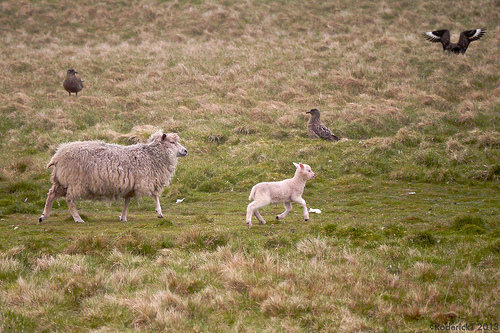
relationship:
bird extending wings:
[421, 16, 489, 58] [421, 23, 486, 41]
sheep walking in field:
[42, 120, 180, 228] [1, 3, 493, 333]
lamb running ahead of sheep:
[239, 152, 316, 224] [42, 120, 180, 228]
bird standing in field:
[303, 102, 342, 148] [1, 3, 493, 333]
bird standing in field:
[60, 63, 86, 96] [1, 3, 493, 333]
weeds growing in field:
[325, 213, 497, 253] [1, 3, 493, 333]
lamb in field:
[239, 152, 316, 224] [1, 3, 493, 333]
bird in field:
[303, 102, 342, 148] [1, 3, 493, 333]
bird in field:
[60, 63, 86, 96] [1, 3, 493, 333]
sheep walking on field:
[42, 120, 180, 228] [1, 3, 493, 333]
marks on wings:
[421, 17, 484, 42] [421, 23, 486, 41]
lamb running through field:
[239, 152, 316, 224] [1, 3, 493, 333]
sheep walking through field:
[42, 120, 180, 228] [1, 3, 493, 333]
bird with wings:
[421, 16, 489, 58] [421, 23, 486, 41]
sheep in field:
[42, 120, 180, 228] [1, 3, 493, 333]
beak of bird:
[304, 111, 312, 117] [303, 102, 342, 148]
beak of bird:
[74, 70, 81, 75] [60, 63, 86, 96]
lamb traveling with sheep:
[239, 152, 316, 224] [42, 120, 180, 228]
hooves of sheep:
[35, 212, 171, 224] [42, 120, 180, 228]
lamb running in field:
[239, 152, 316, 224] [1, 3, 493, 333]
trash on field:
[170, 185, 419, 228] [1, 3, 493, 333]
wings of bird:
[421, 23, 486, 41] [421, 16, 489, 58]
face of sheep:
[169, 136, 189, 156] [42, 120, 180, 228]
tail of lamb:
[245, 187, 256, 200] [239, 152, 316, 224]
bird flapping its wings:
[421, 16, 489, 58] [421, 23, 486, 41]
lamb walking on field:
[239, 152, 316, 224] [1, 3, 493, 333]